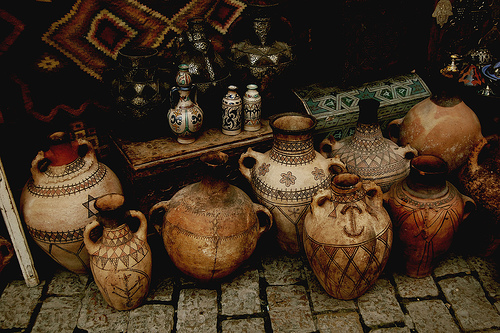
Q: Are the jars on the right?
A: Yes, the jars are on the right of the image.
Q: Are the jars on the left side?
A: No, the jars are on the right of the image.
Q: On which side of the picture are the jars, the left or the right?
A: The jars are on the right of the image.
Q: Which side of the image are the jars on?
A: The jars are on the right of the image.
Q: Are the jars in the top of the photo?
A: Yes, the jars are in the top of the image.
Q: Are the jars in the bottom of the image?
A: No, the jars are in the top of the image.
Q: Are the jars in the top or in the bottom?
A: The jars are in the top of the image.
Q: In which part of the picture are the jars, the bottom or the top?
A: The jars are in the top of the image.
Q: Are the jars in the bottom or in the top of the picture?
A: The jars are in the top of the image.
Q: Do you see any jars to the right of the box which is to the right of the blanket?
A: Yes, there are jars to the right of the box.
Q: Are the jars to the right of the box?
A: Yes, the jars are to the right of the box.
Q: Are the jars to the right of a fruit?
A: No, the jars are to the right of the box.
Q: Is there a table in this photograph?
A: Yes, there is a table.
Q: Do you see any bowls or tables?
A: Yes, there is a table.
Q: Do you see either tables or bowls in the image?
A: Yes, there is a table.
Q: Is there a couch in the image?
A: No, there are no couches.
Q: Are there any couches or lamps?
A: No, there are no couches or lamps.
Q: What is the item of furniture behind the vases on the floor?
A: The piece of furniture is a table.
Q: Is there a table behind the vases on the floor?
A: Yes, there is a table behind the vases.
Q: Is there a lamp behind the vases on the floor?
A: No, there is a table behind the vases.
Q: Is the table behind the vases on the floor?
A: Yes, the table is behind the vases.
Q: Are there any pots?
A: Yes, there is a pot.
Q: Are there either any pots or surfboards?
A: Yes, there is a pot.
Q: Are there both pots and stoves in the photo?
A: No, there is a pot but no stoves.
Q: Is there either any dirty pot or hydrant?
A: Yes, there is a dirty pot.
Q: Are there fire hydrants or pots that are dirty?
A: Yes, the pot is dirty.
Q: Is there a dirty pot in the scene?
A: Yes, there is a dirty pot.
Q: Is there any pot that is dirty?
A: Yes, there is a pot that is dirty.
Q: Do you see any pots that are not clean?
A: Yes, there is a dirty pot.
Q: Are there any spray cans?
A: No, there are no spray cans.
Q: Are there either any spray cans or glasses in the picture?
A: No, there are no spray cans or glasses.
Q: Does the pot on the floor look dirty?
A: Yes, the pot is dirty.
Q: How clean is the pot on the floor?
A: The pot is dirty.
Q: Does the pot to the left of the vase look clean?
A: No, the pot is dirty.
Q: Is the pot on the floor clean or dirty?
A: The pot is dirty.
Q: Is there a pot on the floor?
A: Yes, there is a pot on the floor.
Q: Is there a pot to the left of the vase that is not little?
A: Yes, there is a pot to the left of the vase.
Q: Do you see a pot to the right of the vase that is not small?
A: No, the pot is to the left of the vase.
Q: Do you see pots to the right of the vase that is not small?
A: No, the pot is to the left of the vase.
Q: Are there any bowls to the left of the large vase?
A: No, there is a pot to the left of the vase.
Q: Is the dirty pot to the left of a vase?
A: Yes, the pot is to the left of a vase.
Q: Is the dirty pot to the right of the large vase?
A: No, the pot is to the left of the vase.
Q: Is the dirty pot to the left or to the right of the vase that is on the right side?
A: The pot is to the left of the vase.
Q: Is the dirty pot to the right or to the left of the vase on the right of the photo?
A: The pot is to the left of the vase.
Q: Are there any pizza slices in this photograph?
A: No, there are no pizza slices.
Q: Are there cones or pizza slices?
A: No, there are no pizza slices or cones.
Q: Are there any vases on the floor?
A: Yes, there are vases on the floor.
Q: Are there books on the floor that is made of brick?
A: No, there are vases on the floor.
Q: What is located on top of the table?
A: The vases are on top of the table.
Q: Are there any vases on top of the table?
A: Yes, there are vases on top of the table.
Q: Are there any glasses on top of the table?
A: No, there are vases on top of the table.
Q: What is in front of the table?
A: The vases are in front of the table.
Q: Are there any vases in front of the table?
A: Yes, there are vases in front of the table.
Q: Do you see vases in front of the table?
A: Yes, there are vases in front of the table.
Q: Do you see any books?
A: No, there are no books.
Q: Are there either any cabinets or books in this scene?
A: No, there are no books or cabinets.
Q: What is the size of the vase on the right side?
A: The vase is large.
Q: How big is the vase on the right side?
A: The vase is large.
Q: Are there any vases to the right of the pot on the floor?
A: Yes, there is a vase to the right of the pot.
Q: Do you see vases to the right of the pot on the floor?
A: Yes, there is a vase to the right of the pot.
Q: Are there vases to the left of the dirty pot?
A: No, the vase is to the right of the pot.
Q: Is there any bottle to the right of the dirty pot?
A: No, there is a vase to the right of the pot.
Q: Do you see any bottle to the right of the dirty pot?
A: No, there is a vase to the right of the pot.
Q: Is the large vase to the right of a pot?
A: Yes, the vase is to the right of a pot.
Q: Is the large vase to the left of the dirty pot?
A: No, the vase is to the right of the pot.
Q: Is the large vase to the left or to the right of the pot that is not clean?
A: The vase is to the right of the pot.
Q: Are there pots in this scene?
A: Yes, there is a pot.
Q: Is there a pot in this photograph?
A: Yes, there is a pot.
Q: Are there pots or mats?
A: Yes, there is a pot.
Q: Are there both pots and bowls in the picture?
A: No, there is a pot but no bowls.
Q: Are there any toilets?
A: No, there are no toilets.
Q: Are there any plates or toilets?
A: No, there are no toilets or plates.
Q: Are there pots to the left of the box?
A: Yes, there is a pot to the left of the box.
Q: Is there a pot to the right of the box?
A: No, the pot is to the left of the box.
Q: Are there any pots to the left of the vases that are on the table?
A: Yes, there is a pot to the left of the vases.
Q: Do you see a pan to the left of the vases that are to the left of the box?
A: No, there is a pot to the left of the vases.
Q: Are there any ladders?
A: No, there are no ladders.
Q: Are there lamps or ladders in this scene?
A: No, there are no ladders or lamps.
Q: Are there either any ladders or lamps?
A: No, there are no ladders or lamps.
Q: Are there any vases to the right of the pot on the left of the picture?
A: Yes, there are vases to the right of the pot.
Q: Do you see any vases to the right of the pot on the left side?
A: Yes, there are vases to the right of the pot.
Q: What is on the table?
A: The vases are on the table.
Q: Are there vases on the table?
A: Yes, there are vases on the table.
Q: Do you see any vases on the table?
A: Yes, there are vases on the table.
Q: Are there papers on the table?
A: No, there are vases on the table.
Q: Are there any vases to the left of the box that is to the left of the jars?
A: Yes, there are vases to the left of the box.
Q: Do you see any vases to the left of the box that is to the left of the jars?
A: Yes, there are vases to the left of the box.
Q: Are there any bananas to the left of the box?
A: No, there are vases to the left of the box.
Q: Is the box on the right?
A: Yes, the box is on the right of the image.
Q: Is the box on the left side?
A: No, the box is on the right of the image.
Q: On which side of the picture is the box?
A: The box is on the right of the image.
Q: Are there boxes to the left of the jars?
A: Yes, there is a box to the left of the jars.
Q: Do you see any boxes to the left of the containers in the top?
A: Yes, there is a box to the left of the jars.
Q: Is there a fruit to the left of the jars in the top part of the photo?
A: No, there is a box to the left of the jars.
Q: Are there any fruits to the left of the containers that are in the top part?
A: No, there is a box to the left of the jars.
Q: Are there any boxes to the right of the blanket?
A: Yes, there is a box to the right of the blanket.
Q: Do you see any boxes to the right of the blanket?
A: Yes, there is a box to the right of the blanket.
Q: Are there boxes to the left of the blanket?
A: No, the box is to the right of the blanket.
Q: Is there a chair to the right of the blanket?
A: No, there is a box to the right of the blanket.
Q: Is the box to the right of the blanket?
A: Yes, the box is to the right of the blanket.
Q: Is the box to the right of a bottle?
A: No, the box is to the right of the blanket.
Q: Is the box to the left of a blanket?
A: No, the box is to the right of a blanket.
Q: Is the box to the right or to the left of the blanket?
A: The box is to the right of the blanket.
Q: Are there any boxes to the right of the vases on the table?
A: Yes, there is a box to the right of the vases.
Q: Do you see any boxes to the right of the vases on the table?
A: Yes, there is a box to the right of the vases.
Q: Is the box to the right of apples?
A: No, the box is to the right of the vases.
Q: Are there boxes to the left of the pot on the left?
A: No, the box is to the right of the pot.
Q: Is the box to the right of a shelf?
A: No, the box is to the right of the pot.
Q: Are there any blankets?
A: Yes, there is a blanket.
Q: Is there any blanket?
A: Yes, there is a blanket.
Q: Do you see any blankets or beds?
A: Yes, there is a blanket.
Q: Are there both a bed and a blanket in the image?
A: No, there is a blanket but no beds.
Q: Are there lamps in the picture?
A: No, there are no lamps.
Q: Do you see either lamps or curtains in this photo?
A: No, there are no lamps or curtains.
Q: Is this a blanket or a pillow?
A: This is a blanket.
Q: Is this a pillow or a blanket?
A: This is a blanket.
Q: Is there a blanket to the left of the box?
A: Yes, there is a blanket to the left of the box.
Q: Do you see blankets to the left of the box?
A: Yes, there is a blanket to the left of the box.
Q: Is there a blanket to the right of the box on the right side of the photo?
A: No, the blanket is to the left of the box.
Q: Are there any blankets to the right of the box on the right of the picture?
A: No, the blanket is to the left of the box.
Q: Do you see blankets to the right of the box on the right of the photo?
A: No, the blanket is to the left of the box.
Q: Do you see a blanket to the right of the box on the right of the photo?
A: No, the blanket is to the left of the box.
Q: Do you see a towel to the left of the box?
A: No, there is a blanket to the left of the box.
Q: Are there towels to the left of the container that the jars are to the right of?
A: No, there is a blanket to the left of the box.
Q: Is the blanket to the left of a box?
A: Yes, the blanket is to the left of a box.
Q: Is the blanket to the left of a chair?
A: No, the blanket is to the left of a box.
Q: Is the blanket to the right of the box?
A: No, the blanket is to the left of the box.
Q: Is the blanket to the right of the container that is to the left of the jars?
A: No, the blanket is to the left of the box.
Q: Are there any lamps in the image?
A: No, there are no lamps.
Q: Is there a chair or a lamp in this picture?
A: No, there are no lamps or chairs.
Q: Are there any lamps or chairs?
A: No, there are no lamps or chairs.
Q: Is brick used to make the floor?
A: Yes, the floor is made of brick.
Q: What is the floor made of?
A: The floor is made of brick.